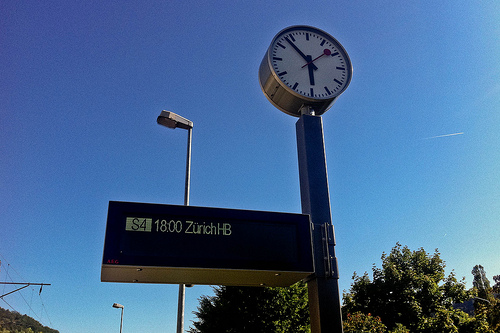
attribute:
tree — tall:
[340, 241, 471, 332]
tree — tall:
[185, 281, 314, 333]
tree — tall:
[452, 264, 499, 333]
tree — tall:
[343, 309, 389, 333]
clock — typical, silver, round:
[257, 24, 353, 119]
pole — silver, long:
[293, 114, 346, 332]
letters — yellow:
[124, 217, 233, 238]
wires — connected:
[1, 256, 47, 325]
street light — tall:
[156, 106, 195, 332]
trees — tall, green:
[186, 241, 498, 332]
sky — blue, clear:
[2, 0, 499, 330]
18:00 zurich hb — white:
[154, 217, 232, 235]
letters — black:
[127, 217, 153, 236]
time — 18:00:
[154, 217, 182, 234]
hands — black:
[282, 35, 317, 86]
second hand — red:
[302, 49, 331, 70]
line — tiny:
[429, 129, 465, 138]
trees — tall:
[0, 308, 59, 333]